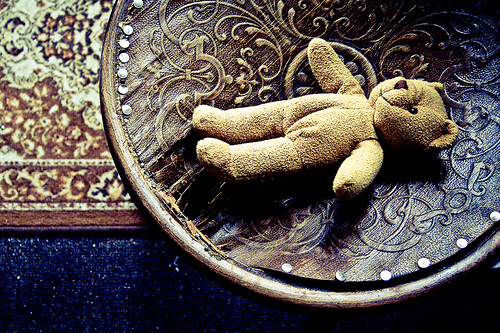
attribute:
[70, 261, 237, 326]
carpet — blue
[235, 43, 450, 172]
bear — brown, teddy bear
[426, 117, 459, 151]
ear — brown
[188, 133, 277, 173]
bears — teddy bear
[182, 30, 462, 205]
bear — teddy bear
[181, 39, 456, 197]
bear — small, brown